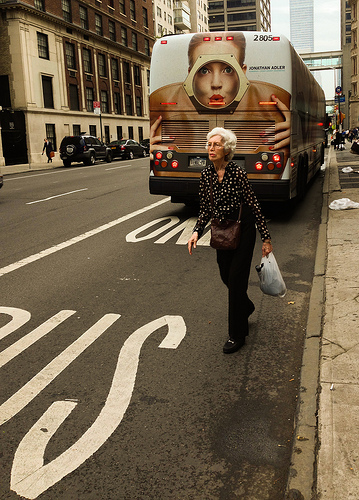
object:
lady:
[149, 31, 291, 159]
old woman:
[185, 119, 289, 358]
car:
[107, 138, 147, 160]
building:
[0, 0, 152, 165]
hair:
[205, 125, 237, 162]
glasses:
[205, 140, 226, 148]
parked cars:
[58, 132, 149, 170]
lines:
[0, 188, 173, 293]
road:
[0, 160, 318, 495]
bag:
[255, 249, 288, 300]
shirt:
[192, 161, 272, 242]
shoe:
[221, 331, 246, 355]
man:
[41, 137, 55, 164]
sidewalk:
[0, 157, 62, 177]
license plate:
[187, 158, 206, 166]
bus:
[148, 31, 325, 224]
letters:
[0, 302, 188, 500]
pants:
[216, 213, 257, 340]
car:
[57, 133, 113, 164]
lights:
[148, 148, 286, 173]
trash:
[325, 194, 359, 214]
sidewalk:
[315, 136, 359, 500]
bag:
[207, 214, 242, 251]